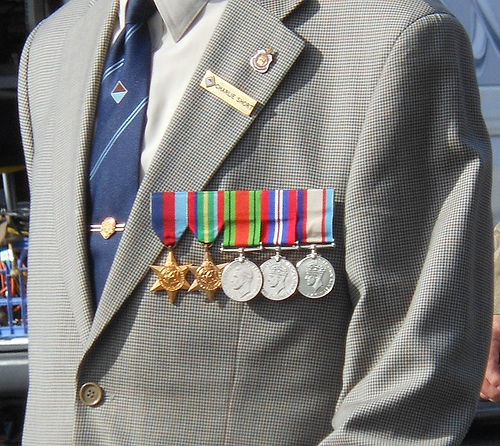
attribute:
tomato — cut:
[442, 394, 496, 442]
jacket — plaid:
[29, 3, 437, 445]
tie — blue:
[72, 7, 155, 295]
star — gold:
[151, 247, 203, 305]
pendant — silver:
[220, 257, 338, 300]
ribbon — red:
[259, 191, 301, 256]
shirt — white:
[112, 10, 245, 165]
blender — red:
[1, 205, 29, 320]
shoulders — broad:
[7, 22, 483, 97]